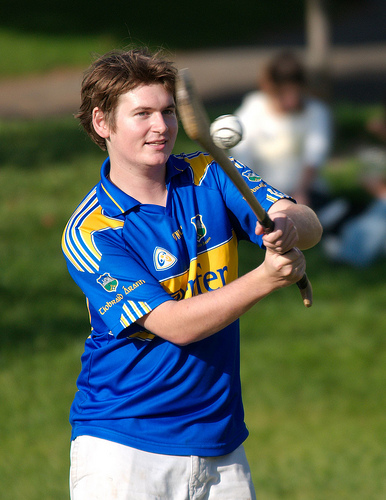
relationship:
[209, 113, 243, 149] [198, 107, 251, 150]
ball hitting ball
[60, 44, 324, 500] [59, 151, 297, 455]
boy wearing jersey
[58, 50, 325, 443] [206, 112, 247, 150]
boy hitting ball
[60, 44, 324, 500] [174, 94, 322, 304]
boy holding mallet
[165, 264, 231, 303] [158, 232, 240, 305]
lettering on background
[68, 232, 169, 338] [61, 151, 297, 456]
sleeve on jersey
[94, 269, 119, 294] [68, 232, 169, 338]
patch on sleeve